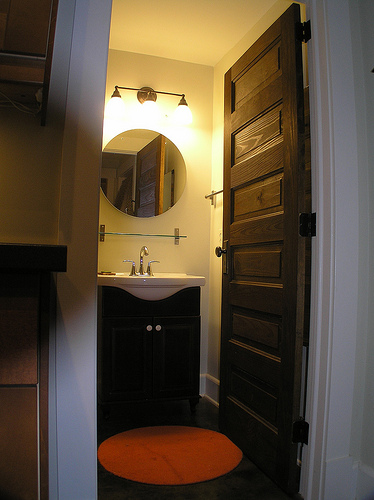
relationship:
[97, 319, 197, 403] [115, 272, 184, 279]
doors under sink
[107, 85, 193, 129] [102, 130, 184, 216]
lights above mirror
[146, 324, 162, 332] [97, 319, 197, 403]
knobs on doors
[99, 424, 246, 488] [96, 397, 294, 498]
rug on floor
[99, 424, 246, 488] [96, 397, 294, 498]
rug orange on floor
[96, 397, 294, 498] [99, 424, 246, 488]
floor has a rug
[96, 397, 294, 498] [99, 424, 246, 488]
floor has an orange rug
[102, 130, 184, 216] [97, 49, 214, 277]
mirror on wall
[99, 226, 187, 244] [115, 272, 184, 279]
towel rack above sink